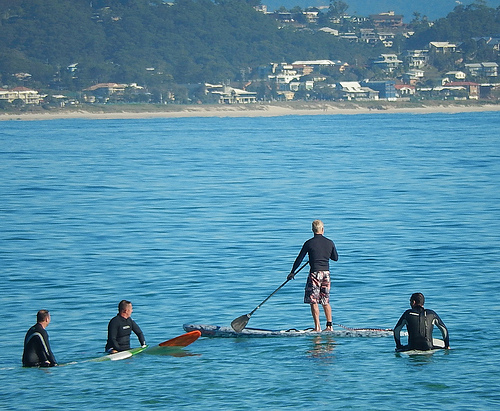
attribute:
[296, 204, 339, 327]
man — bald, looking, paddling, standing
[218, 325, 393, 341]
surfboard — white, blue, long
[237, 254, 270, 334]
paddle — black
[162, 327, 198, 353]
surfboard — orange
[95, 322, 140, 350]
wetsuit — black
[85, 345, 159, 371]
surfboard — green, white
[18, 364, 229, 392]
water — blue, smooth, clear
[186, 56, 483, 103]
buildings — cascading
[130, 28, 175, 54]
leaves — green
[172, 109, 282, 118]
sand — tan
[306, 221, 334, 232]
hair — blonde, blond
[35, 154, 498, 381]
water — blue, calm, rippled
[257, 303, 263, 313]
stripe — white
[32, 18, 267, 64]
forest — green